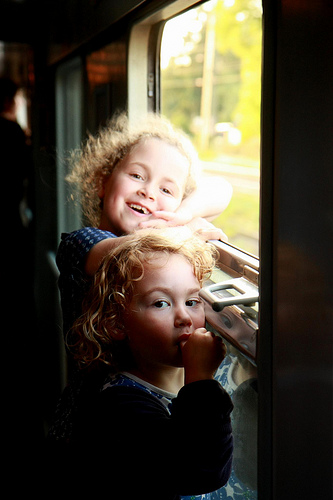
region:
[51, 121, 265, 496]
two young girls riding on a bus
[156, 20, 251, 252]
a window on a bus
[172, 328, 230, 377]
a young girl has her thumb in her mouth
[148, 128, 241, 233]
a young girl has her arm on the window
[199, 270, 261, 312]
a handle to hang on to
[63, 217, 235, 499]
a young girl with blond hair and blue eyes looking at camera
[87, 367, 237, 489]
a little girl wearing a blue sweater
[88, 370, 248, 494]
a little girl wearing a blue and white top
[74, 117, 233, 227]
a girl smiling with blond hair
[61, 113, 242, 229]
a little girl wearing a blue shirt and smiling while looking at camera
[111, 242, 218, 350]
the girl is looking at the camera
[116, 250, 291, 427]
the girl is looking at the camera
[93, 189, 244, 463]
the girl is looking at the camera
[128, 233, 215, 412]
this is a baby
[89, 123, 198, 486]
the babies are two in number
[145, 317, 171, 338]
the baby has a light skin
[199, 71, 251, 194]
this a window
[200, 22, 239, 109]
this is a glass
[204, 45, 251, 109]
the glass is transparent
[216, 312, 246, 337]
this is an image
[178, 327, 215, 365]
the finger is in the mouth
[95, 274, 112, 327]
the hair is long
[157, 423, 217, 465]
this is a pullover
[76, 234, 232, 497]
a small blond child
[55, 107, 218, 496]
a small blond child smiling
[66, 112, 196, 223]
the curly blond hair of a child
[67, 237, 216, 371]
the curly blond hair of a child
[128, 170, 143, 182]
the brown eye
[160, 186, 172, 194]
the brown eye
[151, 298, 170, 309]
the brown eye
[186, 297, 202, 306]
the brown eye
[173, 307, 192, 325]
the small nose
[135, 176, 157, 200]
the small nose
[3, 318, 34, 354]
the background is dark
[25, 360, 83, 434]
the background is dark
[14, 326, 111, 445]
the background is dark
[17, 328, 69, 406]
the background is dark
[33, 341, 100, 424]
the background is dark